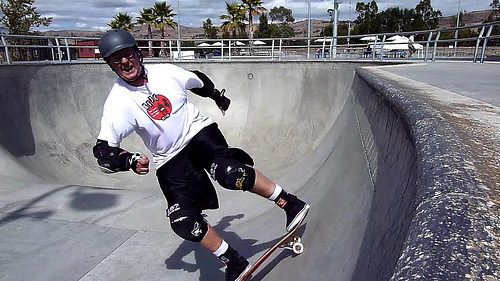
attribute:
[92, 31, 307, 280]
man — happy, senior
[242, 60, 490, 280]
ramp — concrete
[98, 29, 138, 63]
helmet — black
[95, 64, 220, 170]
shirt — white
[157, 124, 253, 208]
shorts — black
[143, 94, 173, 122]
logo — cicular, red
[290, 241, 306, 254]
wheel — white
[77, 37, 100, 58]
building — brown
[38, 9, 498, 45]
moutain — distant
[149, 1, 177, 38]
palm — distant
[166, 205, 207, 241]
knee-pad — black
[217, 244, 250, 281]
shoe — black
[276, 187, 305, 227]
shoe — black